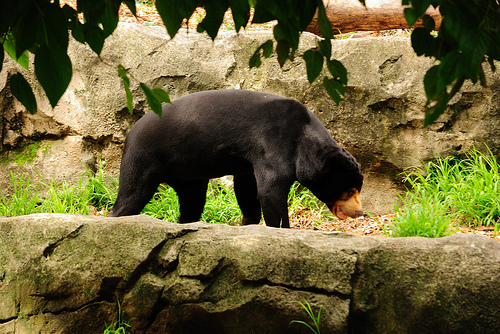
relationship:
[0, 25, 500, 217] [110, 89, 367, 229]
wall behind bear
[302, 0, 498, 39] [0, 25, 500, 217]
tree on wall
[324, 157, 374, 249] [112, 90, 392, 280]
nose on bear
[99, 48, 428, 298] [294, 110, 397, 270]
bear has head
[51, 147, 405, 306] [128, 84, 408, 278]
rock in front of bear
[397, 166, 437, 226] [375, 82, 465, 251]
leaves of tree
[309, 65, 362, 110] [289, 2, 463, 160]
leaf in tree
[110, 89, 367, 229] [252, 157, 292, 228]
bear standing on leg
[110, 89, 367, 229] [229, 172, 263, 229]
bear standing on leg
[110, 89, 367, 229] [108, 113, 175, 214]
bear standing on leg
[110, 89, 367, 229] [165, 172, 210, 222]
bear standing on leg